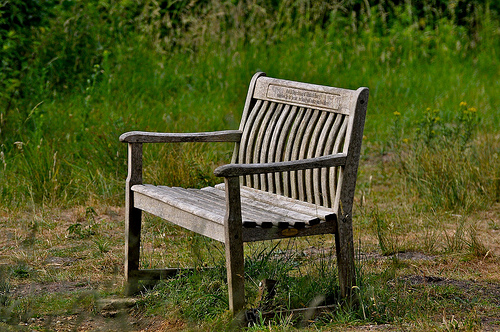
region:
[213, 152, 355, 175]
left arm of bench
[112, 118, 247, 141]
right arm of bench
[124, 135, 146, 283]
right leg of bench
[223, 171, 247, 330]
left front leg of bench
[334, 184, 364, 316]
left back leg of bench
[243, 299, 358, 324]
support between legs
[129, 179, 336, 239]
wooden seat of bench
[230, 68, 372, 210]
back rest of bench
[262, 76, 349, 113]
writing on upper portion of back rest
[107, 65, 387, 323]
wooden bench sitting in weeds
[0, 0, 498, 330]
The field of tall grass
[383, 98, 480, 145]
Yellow flowers in the backgound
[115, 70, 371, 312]
The wooden bench in the field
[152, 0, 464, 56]
The brown tips of the tall grass in background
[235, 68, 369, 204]
Verticle slats of the bench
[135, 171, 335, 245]
Seat portion of the bench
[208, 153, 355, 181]
Right armrest of the bench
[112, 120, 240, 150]
Left armrest of the bench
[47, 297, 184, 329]
Patch of dirt in front of the bench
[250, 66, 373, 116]
Horizontal piece of wood on top of backrest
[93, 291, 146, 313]
large stone on ground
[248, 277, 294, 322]
large wood stump beside bench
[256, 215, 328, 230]
side of weather beaten bench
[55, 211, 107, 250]
clump of grass on ground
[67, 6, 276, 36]
grooves of green trees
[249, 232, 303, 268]
blade of grass under bench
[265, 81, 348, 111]
words embedded in bench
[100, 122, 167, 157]
edge of brown bench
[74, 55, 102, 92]
flowering bud on bush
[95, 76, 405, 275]
large wooden bench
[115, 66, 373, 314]
wooden bench in weeds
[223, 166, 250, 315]
front left leg of bench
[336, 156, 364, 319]
back left leg of bench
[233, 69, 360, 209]
back rest of the bench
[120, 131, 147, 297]
front right leg of bench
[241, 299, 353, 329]
left support between legs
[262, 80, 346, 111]
writing on back rest of bench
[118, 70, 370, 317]
a bench by grass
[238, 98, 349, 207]
a curved back on a bench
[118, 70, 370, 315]
a wooden bench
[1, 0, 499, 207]
tall grass behind a bench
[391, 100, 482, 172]
yellow dandelions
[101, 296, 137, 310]
a stick on the ground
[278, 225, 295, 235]
a gold oval on the bench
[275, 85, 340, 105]
writing on the back rest of the bench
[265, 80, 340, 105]
a rectangle with writing in it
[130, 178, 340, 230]
the seat of the bench has a dip